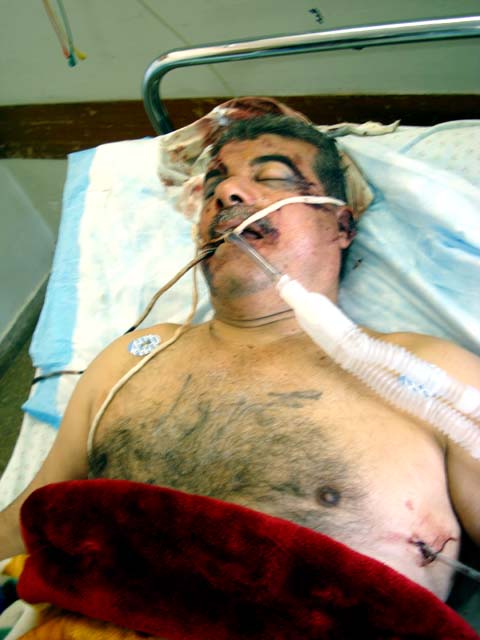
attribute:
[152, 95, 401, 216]
cloth — bloody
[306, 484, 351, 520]
nipple — dark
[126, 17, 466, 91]
railing — shiny , silver 